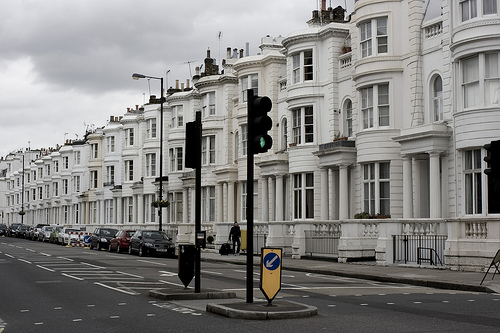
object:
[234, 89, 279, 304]
traffic signal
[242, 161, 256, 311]
pole